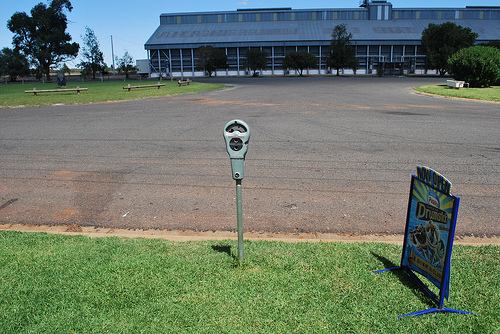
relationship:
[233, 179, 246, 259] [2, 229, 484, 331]
pole in grass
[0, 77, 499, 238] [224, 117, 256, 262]
road passes parking meter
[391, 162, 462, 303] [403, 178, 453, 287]
frame surrounding background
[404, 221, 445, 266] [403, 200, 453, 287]
cone drawn on background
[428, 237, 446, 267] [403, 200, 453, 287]
cone drawn on background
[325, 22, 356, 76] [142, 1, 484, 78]
tree standing in front of building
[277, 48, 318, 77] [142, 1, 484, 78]
tree standing in front of building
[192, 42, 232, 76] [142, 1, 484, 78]
tree standing in front of building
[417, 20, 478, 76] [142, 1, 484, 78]
tree standing in front of building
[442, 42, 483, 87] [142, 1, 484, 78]
bush standing in front of building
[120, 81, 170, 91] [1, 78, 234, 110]
wooden bench sitting in grass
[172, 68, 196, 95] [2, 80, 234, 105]
bench sitting in grass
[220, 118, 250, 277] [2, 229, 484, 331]
metal pole standing in grass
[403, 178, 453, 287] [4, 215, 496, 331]
background standing in grass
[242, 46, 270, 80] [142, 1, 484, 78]
tree standing in front of building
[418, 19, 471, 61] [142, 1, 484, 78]
large tree standing in front of building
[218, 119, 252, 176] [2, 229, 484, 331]
parking meter standing in grass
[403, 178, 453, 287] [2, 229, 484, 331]
background standing in grass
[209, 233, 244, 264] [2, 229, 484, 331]
shadow casted in grass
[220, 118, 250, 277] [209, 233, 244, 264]
metal pole casting shadow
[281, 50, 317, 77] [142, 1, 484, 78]
tree standing in front of building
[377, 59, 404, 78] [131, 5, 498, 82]
entrance leading to building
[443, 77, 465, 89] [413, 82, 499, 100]
bench sitting in grass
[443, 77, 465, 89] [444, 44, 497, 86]
bench sitting in front of bush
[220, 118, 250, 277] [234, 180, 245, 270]
metal pole mounted on pole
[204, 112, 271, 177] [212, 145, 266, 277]
parking meter mounted on metal pole